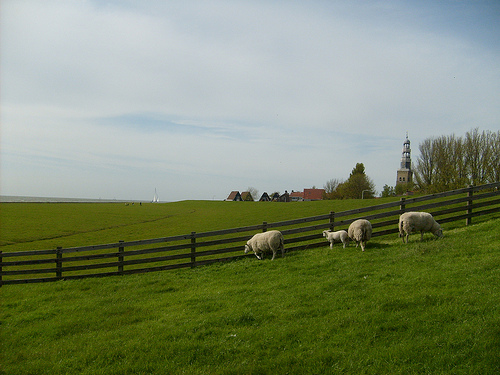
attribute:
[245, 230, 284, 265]
sheep — white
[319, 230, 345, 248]
sheep — young, baby, white, small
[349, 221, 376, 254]
sheep — white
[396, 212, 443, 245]
sheep — white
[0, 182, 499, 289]
fence — gray, wood, wooden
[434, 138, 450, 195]
tree — green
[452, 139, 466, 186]
tree — green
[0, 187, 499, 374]
hill — grassy, green, long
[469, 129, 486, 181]
tree — green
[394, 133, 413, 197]
building — tall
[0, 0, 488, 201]
sky — white, cloudy, clear, clouded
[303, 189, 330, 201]
roof — pointy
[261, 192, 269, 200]
roof — pointy, red